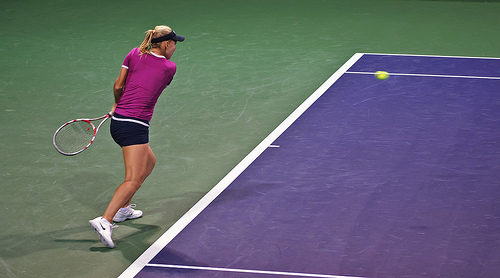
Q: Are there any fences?
A: No, there are no fences.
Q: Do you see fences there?
A: No, there are no fences.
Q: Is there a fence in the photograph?
A: No, there are no fences.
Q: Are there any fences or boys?
A: No, there are no fences or boys.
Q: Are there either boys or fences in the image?
A: No, there are no fences or boys.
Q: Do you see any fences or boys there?
A: No, there are no fences or boys.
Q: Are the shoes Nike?
A: Yes, the shoes are nike.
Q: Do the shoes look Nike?
A: Yes, the shoes are nike.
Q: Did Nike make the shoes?
A: Yes, the shoes were made by nike.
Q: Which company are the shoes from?
A: The shoes are from nike.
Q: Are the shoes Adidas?
A: No, the shoes are nike.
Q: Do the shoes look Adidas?
A: No, the shoes are nike.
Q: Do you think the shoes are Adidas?
A: No, the shoes are nike.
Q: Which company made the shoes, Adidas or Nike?
A: The shoes were made nike.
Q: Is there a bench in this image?
A: No, there are no benches.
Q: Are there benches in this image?
A: No, there are no benches.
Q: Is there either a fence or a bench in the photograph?
A: No, there are no benches or fences.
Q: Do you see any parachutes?
A: No, there are no parachutes.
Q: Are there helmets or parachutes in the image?
A: No, there are no parachutes or helmets.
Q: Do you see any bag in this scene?
A: No, there are no bags.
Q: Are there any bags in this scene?
A: No, there are no bags.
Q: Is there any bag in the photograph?
A: No, there are no bags.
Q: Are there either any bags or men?
A: No, there are no bags or men.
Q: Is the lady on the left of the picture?
A: Yes, the lady is on the left of the image.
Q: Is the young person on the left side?
A: Yes, the lady is on the left of the image.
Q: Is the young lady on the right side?
A: No, the lady is on the left of the image.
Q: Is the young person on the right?
A: No, the lady is on the left of the image.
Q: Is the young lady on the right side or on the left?
A: The lady is on the left of the image.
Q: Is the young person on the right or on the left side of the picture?
A: The lady is on the left of the image.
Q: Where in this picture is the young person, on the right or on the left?
A: The lady is on the left of the image.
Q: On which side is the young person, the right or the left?
A: The lady is on the left of the image.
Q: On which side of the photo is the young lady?
A: The lady is on the left of the image.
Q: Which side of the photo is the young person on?
A: The lady is on the left of the image.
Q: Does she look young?
A: Yes, the lady is young.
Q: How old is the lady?
A: The lady is young.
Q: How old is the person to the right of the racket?
A: The lady is young.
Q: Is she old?
A: No, the lady is young.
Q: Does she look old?
A: No, the lady is young.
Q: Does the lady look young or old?
A: The lady is young.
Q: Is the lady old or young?
A: The lady is young.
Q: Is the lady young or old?
A: The lady is young.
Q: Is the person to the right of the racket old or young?
A: The lady is young.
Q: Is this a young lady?
A: Yes, this is a young lady.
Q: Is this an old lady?
A: No, this is a young lady.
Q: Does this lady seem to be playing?
A: Yes, the lady is playing.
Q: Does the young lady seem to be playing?
A: Yes, the lady is playing.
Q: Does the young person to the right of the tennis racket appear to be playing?
A: Yes, the lady is playing.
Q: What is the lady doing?
A: The lady is playing.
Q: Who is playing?
A: The lady is playing.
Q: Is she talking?
A: No, the lady is playing.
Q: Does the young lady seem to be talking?
A: No, the lady is playing.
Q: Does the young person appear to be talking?
A: No, the lady is playing.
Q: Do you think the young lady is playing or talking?
A: The lady is playing.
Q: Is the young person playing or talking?
A: The lady is playing.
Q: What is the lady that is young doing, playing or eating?
A: The lady is playing.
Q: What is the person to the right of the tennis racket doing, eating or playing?
A: The lady is playing.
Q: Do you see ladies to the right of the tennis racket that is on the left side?
A: Yes, there is a lady to the right of the racket.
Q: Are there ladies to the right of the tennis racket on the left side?
A: Yes, there is a lady to the right of the racket.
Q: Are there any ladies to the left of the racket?
A: No, the lady is to the right of the racket.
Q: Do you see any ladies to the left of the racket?
A: No, the lady is to the right of the racket.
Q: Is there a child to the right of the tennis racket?
A: No, there is a lady to the right of the tennis racket.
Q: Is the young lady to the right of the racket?
A: Yes, the lady is to the right of the racket.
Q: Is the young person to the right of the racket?
A: Yes, the lady is to the right of the racket.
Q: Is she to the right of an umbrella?
A: No, the lady is to the right of the racket.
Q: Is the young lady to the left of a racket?
A: No, the lady is to the right of a racket.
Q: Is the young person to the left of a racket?
A: No, the lady is to the right of a racket.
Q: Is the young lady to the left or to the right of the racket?
A: The lady is to the right of the racket.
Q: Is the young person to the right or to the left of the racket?
A: The lady is to the right of the racket.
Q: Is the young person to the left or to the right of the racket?
A: The lady is to the right of the racket.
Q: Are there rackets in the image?
A: Yes, there is a racket.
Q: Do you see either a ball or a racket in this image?
A: Yes, there is a racket.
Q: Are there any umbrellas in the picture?
A: No, there are no umbrellas.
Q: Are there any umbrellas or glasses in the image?
A: No, there are no umbrellas or glasses.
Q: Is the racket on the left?
A: Yes, the racket is on the left of the image.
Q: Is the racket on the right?
A: No, the racket is on the left of the image.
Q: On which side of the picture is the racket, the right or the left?
A: The racket is on the left of the image.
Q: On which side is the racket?
A: The racket is on the left of the image.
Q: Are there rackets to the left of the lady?
A: Yes, there is a racket to the left of the lady.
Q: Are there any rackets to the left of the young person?
A: Yes, there is a racket to the left of the lady.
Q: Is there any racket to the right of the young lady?
A: No, the racket is to the left of the lady.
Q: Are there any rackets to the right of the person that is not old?
A: No, the racket is to the left of the lady.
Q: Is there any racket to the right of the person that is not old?
A: No, the racket is to the left of the lady.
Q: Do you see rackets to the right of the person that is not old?
A: No, the racket is to the left of the lady.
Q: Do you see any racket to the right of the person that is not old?
A: No, the racket is to the left of the lady.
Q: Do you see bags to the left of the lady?
A: No, there is a racket to the left of the lady.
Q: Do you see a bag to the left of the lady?
A: No, there is a racket to the left of the lady.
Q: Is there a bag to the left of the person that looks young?
A: No, there is a racket to the left of the lady.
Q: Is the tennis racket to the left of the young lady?
A: Yes, the tennis racket is to the left of the lady.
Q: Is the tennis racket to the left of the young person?
A: Yes, the tennis racket is to the left of the lady.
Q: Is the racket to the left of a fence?
A: No, the racket is to the left of the lady.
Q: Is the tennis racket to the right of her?
A: No, the tennis racket is to the left of the lady.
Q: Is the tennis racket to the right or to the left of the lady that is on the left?
A: The tennis racket is to the left of the lady.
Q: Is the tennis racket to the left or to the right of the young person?
A: The tennis racket is to the left of the lady.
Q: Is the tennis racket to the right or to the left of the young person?
A: The tennis racket is to the left of the lady.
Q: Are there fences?
A: No, there are no fences.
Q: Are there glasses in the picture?
A: No, there are no glasses.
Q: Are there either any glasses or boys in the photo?
A: No, there are no glasses or boys.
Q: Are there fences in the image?
A: No, there are no fences.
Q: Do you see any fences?
A: No, there are no fences.